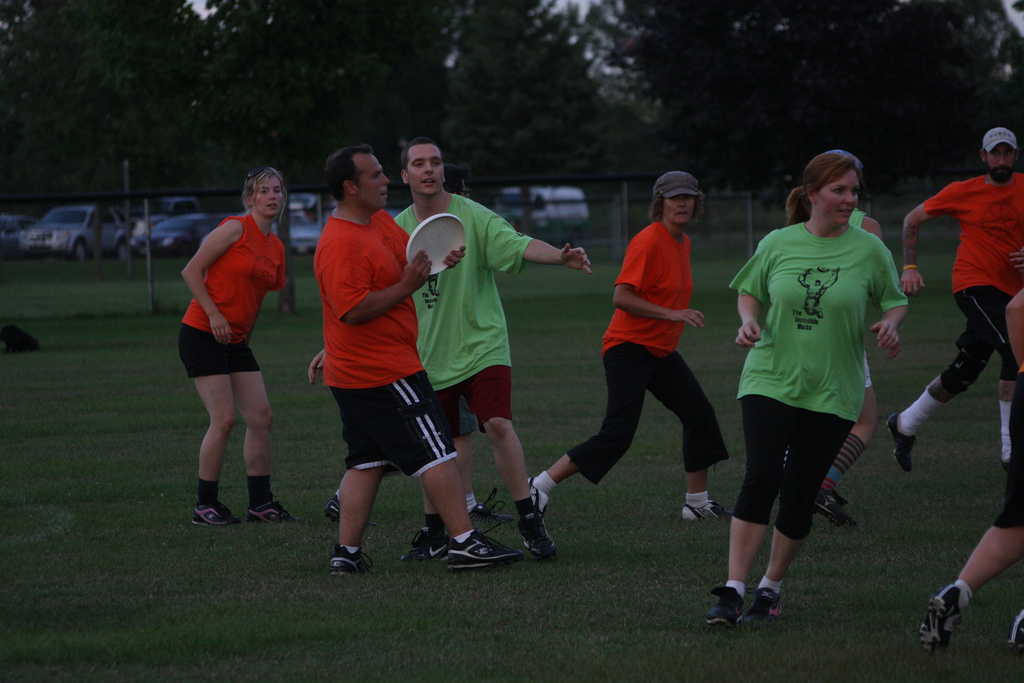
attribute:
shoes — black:
[923, 578, 1022, 655]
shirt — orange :
[178, 200, 293, 350]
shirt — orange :
[615, 220, 702, 367]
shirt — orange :
[318, 207, 408, 389]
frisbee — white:
[403, 205, 470, 273]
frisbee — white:
[402, 204, 469, 310]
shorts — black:
[168, 318, 263, 382]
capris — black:
[740, 391, 839, 544]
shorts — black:
[333, 366, 454, 469]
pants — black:
[592, 349, 720, 485]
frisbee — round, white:
[403, 208, 464, 273]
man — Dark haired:
[406, 207, 471, 294]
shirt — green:
[398, 189, 612, 416]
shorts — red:
[435, 333, 529, 467]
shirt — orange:
[139, 208, 300, 362]